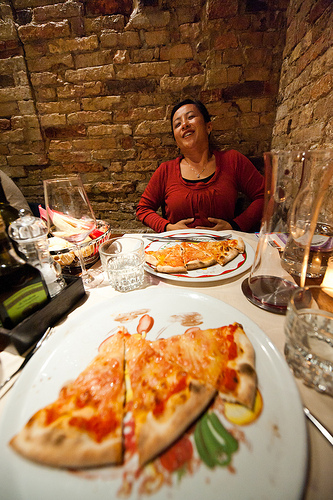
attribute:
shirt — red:
[132, 148, 263, 230]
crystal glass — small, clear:
[97, 233, 149, 299]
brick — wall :
[101, 79, 157, 94]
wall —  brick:
[96, 45, 171, 107]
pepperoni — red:
[162, 433, 192, 468]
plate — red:
[177, 262, 245, 284]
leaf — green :
[162, 405, 233, 451]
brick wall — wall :
[2, 0, 332, 229]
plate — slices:
[131, 223, 261, 291]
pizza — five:
[180, 237, 216, 269]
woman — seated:
[132, 95, 279, 235]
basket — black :
[0, 274, 87, 352]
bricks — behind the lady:
[65, 39, 140, 160]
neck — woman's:
[178, 148, 216, 179]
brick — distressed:
[183, 60, 264, 109]